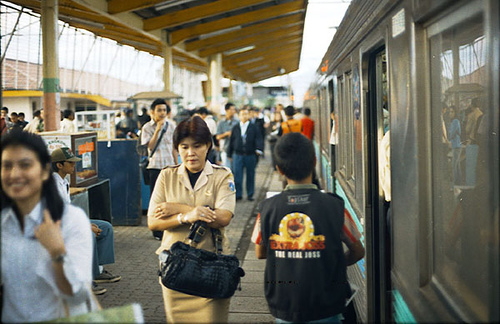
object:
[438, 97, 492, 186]
reflections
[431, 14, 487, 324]
window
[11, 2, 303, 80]
awning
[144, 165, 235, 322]
suit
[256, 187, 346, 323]
vest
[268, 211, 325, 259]
logo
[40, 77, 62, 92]
stripe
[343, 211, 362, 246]
sleeves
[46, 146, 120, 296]
boy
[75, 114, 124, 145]
railing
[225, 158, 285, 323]
sidewalk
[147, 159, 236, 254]
shirt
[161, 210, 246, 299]
bag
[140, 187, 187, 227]
arms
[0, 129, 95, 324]
woman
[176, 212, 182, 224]
watch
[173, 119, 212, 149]
hair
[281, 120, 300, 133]
shirt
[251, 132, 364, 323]
boy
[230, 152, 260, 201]
pats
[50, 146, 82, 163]
hat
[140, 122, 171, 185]
handbag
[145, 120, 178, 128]
shoulder